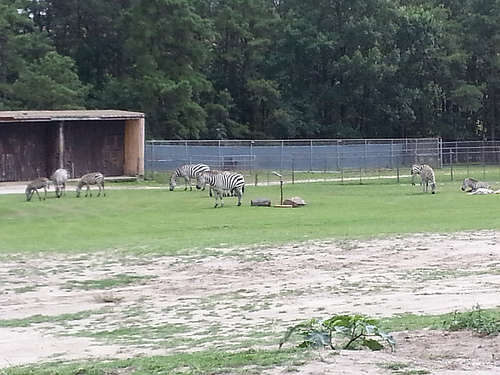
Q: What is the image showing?
A: It is showing a pasture.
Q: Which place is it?
A: It is a pasture.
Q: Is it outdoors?
A: Yes, it is outdoors.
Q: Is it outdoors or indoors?
A: It is outdoors.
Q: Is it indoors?
A: No, it is outdoors.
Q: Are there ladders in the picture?
A: No, there are no ladders.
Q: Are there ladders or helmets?
A: No, there are no ladders or helmets.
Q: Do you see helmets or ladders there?
A: No, there are no ladders or helmets.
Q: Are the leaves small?
A: Yes, the leaves are small.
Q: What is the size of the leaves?
A: The leaves are small.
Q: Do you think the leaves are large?
A: No, the leaves are small.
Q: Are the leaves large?
A: No, the leaves are small.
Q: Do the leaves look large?
A: No, the leaves are small.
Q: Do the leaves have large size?
A: No, the leaves are small.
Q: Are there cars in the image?
A: No, there are no cars.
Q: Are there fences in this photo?
A: Yes, there is a fence.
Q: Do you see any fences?
A: Yes, there is a fence.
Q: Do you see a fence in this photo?
A: Yes, there is a fence.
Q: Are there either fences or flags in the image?
A: Yes, there is a fence.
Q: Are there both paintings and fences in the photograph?
A: No, there is a fence but no paintings.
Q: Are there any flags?
A: No, there are no flags.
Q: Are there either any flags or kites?
A: No, there are no flags or kites.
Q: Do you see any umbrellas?
A: No, there are no umbrellas.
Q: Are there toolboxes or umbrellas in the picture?
A: No, there are no umbrellas or toolboxes.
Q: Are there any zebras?
A: Yes, there is a zebra.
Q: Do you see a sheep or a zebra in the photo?
A: Yes, there is a zebra.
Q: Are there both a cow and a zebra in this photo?
A: No, there is a zebra but no cows.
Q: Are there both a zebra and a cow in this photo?
A: No, there is a zebra but no cows.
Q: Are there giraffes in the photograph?
A: No, there are no giraffes.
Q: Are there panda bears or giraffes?
A: No, there are no giraffes or panda bears.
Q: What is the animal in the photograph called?
A: The animal is a zebra.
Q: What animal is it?
A: The animal is a zebra.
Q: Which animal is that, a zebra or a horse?
A: This is a zebra.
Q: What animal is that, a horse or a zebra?
A: This is a zebra.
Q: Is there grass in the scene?
A: Yes, there is grass.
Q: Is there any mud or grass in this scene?
A: Yes, there is grass.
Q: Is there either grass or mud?
A: Yes, there is grass.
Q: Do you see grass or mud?
A: Yes, there is grass.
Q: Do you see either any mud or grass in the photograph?
A: Yes, there is grass.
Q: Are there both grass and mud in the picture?
A: No, there is grass but no mud.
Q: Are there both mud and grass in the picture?
A: No, there is grass but no mud.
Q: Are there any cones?
A: No, there are no cones.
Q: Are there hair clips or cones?
A: No, there are no cones or hair clips.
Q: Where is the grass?
A: The grass is on the ground.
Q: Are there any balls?
A: No, there are no balls.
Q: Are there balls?
A: No, there are no balls.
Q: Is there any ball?
A: No, there are no balls.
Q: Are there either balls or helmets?
A: No, there are no balls or helmets.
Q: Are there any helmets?
A: No, there are no helmets.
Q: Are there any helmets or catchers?
A: No, there are no helmets or catchers.